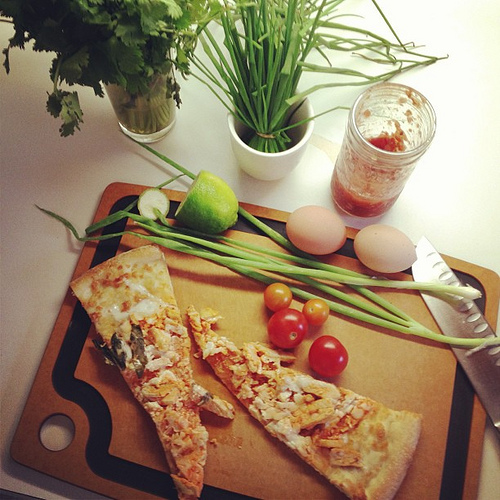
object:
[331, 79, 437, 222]
jar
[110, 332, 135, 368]
mushroom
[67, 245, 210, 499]
pizza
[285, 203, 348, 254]
eggs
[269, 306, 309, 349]
tomatoes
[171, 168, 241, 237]
lime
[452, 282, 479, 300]
green onions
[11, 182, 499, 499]
chopping board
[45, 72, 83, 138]
herbs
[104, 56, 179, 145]
glass jar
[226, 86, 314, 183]
cup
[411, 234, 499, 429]
knife blade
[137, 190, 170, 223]
piece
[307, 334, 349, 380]
tomato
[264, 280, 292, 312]
tomato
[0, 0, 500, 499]
counter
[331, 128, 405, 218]
tomato suace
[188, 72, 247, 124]
herbs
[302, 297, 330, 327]
tomatoes